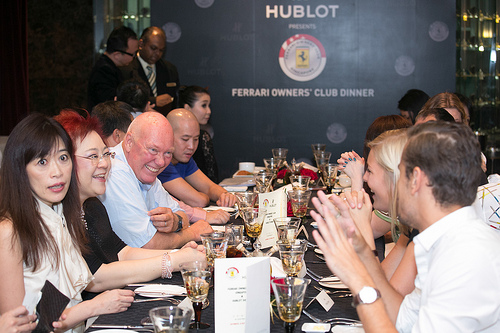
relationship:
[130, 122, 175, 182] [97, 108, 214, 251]
face belonging to man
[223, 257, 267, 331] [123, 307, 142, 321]
menu on table